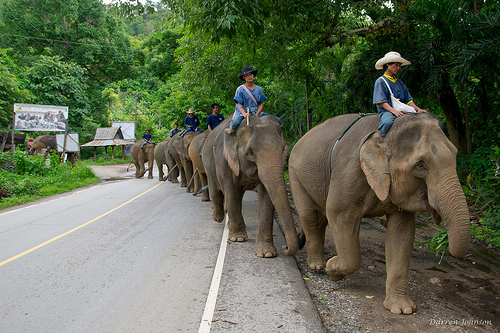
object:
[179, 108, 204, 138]
man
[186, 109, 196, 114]
hat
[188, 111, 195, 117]
head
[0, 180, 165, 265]
line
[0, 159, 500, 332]
road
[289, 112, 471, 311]
elephant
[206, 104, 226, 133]
people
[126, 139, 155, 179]
elephant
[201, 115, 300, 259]
elephants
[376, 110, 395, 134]
jeans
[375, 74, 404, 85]
shoulder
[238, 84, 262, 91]
shoulder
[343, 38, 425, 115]
man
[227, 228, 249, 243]
feet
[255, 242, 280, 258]
feet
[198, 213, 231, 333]
white line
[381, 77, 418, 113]
bag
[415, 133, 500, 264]
grass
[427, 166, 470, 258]
trunk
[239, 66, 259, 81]
hat.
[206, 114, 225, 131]
shirt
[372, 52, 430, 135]
man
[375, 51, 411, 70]
hat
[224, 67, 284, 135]
man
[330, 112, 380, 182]
strap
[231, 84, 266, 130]
suit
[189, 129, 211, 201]
elephants.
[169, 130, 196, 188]
elephant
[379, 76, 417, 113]
satchel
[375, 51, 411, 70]
white hat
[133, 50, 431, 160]
men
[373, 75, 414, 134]
shirt